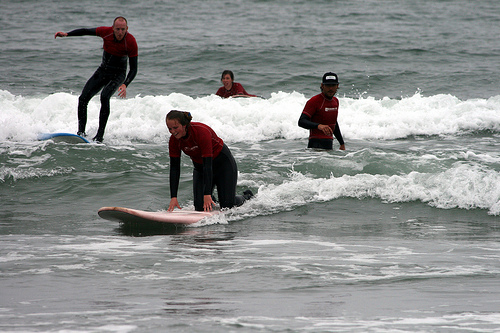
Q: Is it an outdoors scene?
A: Yes, it is outdoors.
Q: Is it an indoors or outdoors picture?
A: It is outdoors.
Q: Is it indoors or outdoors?
A: It is outdoors.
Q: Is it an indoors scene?
A: No, it is outdoors.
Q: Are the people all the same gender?
A: No, they are both male and female.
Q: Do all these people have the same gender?
A: No, they are both male and female.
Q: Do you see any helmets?
A: No, there are no helmets.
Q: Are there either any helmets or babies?
A: No, there are no helmets or babies.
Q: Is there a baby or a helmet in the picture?
A: No, there are no helmets or babies.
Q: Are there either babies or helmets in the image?
A: No, there are no helmets or babies.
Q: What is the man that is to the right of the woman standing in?
A: The man is standing in the water.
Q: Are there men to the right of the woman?
A: Yes, there is a man to the right of the woman.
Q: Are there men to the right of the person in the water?
A: Yes, there is a man to the right of the woman.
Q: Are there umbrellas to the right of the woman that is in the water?
A: No, there is a man to the right of the woman.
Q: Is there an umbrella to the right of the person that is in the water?
A: No, there is a man to the right of the woman.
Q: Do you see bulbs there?
A: No, there are no bulbs.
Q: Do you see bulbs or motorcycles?
A: No, there are no bulbs or motorcycles.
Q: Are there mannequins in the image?
A: No, there are no mannequins.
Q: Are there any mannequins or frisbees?
A: No, there are no mannequins or frisbees.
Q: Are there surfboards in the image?
A: Yes, there is a surfboard.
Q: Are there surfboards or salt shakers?
A: Yes, there is a surfboard.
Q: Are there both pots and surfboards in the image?
A: No, there is a surfboard but no pots.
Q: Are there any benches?
A: No, there are no benches.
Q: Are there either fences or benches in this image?
A: No, there are no benches or fences.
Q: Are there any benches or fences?
A: No, there are no benches or fences.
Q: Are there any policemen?
A: No, there are no policemen.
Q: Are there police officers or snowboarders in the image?
A: No, there are no police officers or snowboarders.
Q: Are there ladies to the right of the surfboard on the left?
A: Yes, there is a lady to the right of the surfboard.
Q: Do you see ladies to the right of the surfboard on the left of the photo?
A: Yes, there is a lady to the right of the surfboard.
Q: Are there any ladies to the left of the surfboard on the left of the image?
A: No, the lady is to the right of the surfboard.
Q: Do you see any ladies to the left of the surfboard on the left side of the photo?
A: No, the lady is to the right of the surfboard.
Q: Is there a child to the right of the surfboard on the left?
A: No, there is a lady to the right of the surfboard.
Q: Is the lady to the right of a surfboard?
A: Yes, the lady is to the right of a surfboard.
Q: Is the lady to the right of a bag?
A: No, the lady is to the right of a surfboard.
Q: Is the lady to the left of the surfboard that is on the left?
A: No, the lady is to the right of the surfboard.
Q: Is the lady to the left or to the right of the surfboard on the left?
A: The lady is to the right of the surfboard.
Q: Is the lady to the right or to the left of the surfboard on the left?
A: The lady is to the right of the surfboard.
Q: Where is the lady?
A: The lady is in the ocean.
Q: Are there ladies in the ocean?
A: Yes, there is a lady in the ocean.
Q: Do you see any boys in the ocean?
A: No, there is a lady in the ocean.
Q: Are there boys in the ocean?
A: No, there is a lady in the ocean.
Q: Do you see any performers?
A: No, there are no performers.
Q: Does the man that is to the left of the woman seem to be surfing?
A: Yes, the man is surfing.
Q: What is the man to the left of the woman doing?
A: The man is surfing.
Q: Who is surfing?
A: The man is surfing.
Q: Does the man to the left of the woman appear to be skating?
A: No, the man is surfing.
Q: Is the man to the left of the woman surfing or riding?
A: The man is surfing.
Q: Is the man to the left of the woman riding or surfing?
A: The man is surfing.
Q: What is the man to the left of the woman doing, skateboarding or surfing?
A: The man is surfing.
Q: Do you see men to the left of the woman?
A: Yes, there is a man to the left of the woman.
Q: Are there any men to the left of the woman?
A: Yes, there is a man to the left of the woman.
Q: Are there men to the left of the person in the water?
A: Yes, there is a man to the left of the woman.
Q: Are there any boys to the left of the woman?
A: No, there is a man to the left of the woman.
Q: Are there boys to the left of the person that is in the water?
A: No, there is a man to the left of the woman.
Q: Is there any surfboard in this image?
A: Yes, there is a surfboard.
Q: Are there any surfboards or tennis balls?
A: Yes, there is a surfboard.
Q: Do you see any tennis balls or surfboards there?
A: Yes, there is a surfboard.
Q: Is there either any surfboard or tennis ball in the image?
A: Yes, there is a surfboard.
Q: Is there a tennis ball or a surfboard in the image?
A: Yes, there is a surfboard.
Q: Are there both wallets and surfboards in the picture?
A: No, there is a surfboard but no wallets.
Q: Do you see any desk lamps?
A: No, there are no desk lamps.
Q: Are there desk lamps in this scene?
A: No, there are no desk lamps.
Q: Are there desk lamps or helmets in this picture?
A: No, there are no desk lamps or helmets.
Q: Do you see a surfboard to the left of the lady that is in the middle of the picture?
A: Yes, there is a surfboard to the left of the lady.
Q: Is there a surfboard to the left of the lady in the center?
A: Yes, there is a surfboard to the left of the lady.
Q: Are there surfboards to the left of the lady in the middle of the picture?
A: Yes, there is a surfboard to the left of the lady.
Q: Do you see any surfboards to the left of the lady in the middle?
A: Yes, there is a surfboard to the left of the lady.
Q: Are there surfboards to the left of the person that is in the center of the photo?
A: Yes, there is a surfboard to the left of the lady.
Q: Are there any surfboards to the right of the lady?
A: No, the surfboard is to the left of the lady.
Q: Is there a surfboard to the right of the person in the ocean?
A: No, the surfboard is to the left of the lady.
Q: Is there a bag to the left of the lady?
A: No, there is a surfboard to the left of the lady.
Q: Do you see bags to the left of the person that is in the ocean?
A: No, there is a surfboard to the left of the lady.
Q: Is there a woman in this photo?
A: Yes, there is a woman.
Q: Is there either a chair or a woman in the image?
A: Yes, there is a woman.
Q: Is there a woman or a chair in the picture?
A: Yes, there is a woman.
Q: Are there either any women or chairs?
A: Yes, there is a woman.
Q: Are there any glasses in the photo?
A: No, there are no glasses.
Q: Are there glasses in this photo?
A: No, there are no glasses.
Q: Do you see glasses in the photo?
A: No, there are no glasses.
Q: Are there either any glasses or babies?
A: No, there are no glasses or babies.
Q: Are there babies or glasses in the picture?
A: No, there are no glasses or babies.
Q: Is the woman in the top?
A: Yes, the woman is in the top of the image.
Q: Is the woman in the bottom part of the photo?
A: No, the woman is in the top of the image.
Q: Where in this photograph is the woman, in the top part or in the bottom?
A: The woman is in the top of the image.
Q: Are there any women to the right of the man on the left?
A: Yes, there is a woman to the right of the man.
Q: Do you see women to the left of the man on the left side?
A: No, the woman is to the right of the man.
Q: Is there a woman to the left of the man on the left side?
A: No, the woman is to the right of the man.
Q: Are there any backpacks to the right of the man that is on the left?
A: No, there is a woman to the right of the man.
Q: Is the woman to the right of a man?
A: Yes, the woman is to the right of a man.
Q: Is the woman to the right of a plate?
A: No, the woman is to the right of a man.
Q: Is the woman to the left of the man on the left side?
A: No, the woman is to the right of the man.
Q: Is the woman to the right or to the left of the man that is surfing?
A: The woman is to the right of the man.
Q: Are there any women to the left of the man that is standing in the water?
A: Yes, there is a woman to the left of the man.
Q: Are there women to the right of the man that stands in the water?
A: No, the woman is to the left of the man.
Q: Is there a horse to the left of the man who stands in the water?
A: No, there is a woman to the left of the man.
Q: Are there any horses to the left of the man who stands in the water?
A: No, there is a woman to the left of the man.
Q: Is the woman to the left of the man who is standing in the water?
A: Yes, the woman is to the left of the man.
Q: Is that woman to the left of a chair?
A: No, the woman is to the left of the man.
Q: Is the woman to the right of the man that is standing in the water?
A: No, the woman is to the left of the man.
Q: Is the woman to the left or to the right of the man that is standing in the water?
A: The woman is to the left of the man.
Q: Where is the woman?
A: The woman is in the water.